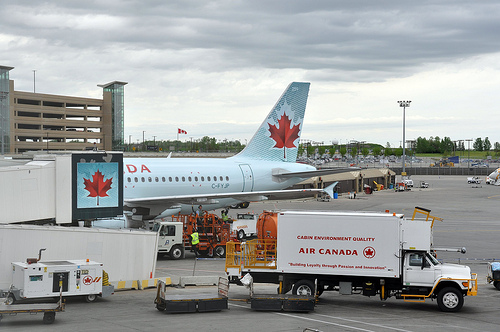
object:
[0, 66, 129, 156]
building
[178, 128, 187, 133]
canada flag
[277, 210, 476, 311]
truck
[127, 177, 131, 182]
windows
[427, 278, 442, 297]
bars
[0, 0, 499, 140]
sky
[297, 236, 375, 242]
lettering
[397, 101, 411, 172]
floodlight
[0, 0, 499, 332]
photo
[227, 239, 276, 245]
railing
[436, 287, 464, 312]
tire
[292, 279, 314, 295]
tire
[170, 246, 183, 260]
tire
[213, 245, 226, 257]
tire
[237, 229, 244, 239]
tire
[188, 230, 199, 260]
man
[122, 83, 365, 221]
airplane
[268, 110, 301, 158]
leaf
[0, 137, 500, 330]
airport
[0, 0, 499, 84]
cloudy